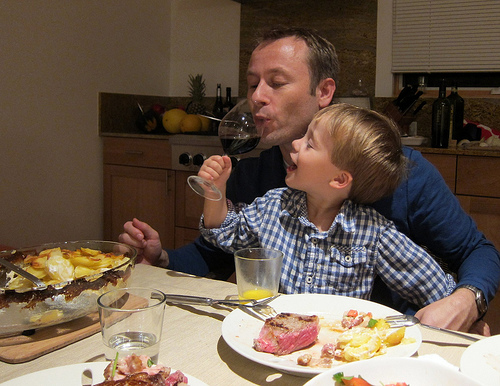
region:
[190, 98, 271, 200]
a glass with red wine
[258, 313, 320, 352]
a piece of meat on the plate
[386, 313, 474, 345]
a fork leaning on the plate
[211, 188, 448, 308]
a blue checkered shirt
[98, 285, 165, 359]
a glass with water in it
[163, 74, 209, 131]
fruit on the counter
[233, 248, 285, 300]
a glass with juice in it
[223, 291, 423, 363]
a plate of food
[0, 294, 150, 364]
a wood hot plate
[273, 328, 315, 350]
the meat is pink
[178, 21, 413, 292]
A child helping his father drink wine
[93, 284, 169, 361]
a glass of water on the table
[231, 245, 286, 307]
a glass of juice on the table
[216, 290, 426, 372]
a white plate on the table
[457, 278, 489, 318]
a watch on the wrist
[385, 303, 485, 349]
fork on the plate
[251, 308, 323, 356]
meat on plate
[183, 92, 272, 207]
glass of drink the guy is drinking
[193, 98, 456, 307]
boy on man's lap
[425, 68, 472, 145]
bottles on the counter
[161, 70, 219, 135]
fruits on the counter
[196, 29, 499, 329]
boy feeding man wine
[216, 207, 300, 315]
glass of orange juice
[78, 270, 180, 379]
glass of water on table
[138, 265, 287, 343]
silver spoon on plate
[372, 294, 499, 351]
silver fork on plate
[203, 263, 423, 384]
white plate of food on table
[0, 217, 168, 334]
dish of potato scallops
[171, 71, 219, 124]
pineapple on table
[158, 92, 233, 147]
fruit on table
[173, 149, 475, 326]
boy wearing blue and white shirt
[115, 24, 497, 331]
Man sitting by the table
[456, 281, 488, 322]
Watch on the man's wrist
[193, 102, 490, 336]
Boy sitting in front of the man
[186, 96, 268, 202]
Wine glass in the boy's hand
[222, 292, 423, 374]
Plate on the tbale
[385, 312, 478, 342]
Fork on the plate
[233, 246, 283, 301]
Juice glass on the table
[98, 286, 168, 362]
Water glass on the table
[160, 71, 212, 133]
Fruits on the kitchen counter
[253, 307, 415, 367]
Food on the plate